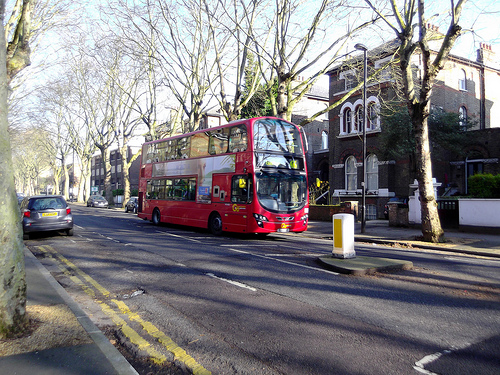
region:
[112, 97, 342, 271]
this is a bus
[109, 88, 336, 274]
the bus is a double decker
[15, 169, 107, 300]
car on side of the street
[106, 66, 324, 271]
the bus is red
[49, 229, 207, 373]
yellow lines on the street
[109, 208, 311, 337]
white lines on the street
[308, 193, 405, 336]
median in the street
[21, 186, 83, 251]
this is a car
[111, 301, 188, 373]
these are yellow lines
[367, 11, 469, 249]
this is a tree without leaves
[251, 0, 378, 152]
this is a tree without leaves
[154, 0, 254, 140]
this is a tree without leaves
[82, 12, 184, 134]
this is a tree without leaves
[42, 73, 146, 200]
this is a tree without leaves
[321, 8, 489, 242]
this is a building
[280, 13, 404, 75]
this is a branch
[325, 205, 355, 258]
white trash container on side of road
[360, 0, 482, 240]
large bare tree in the sunlight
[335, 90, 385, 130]
white framed windows on building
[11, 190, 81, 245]
dark gray compact car parked on road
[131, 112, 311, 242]
double stacked red travel bus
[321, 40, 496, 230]
large dark building next to buss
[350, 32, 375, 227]
tall light post in front of buiding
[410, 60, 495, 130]
shadow of building on the building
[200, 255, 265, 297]
white traffic line on asphalt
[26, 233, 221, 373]
double yellow line painted on asphalt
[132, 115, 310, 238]
Red double decker bus on the street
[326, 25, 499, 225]
Building with white trim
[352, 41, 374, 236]
Street lamp on the curb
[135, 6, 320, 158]
Trees behind a bus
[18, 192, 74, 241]
Grey car parked on the side of the road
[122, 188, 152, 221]
Car behind the bus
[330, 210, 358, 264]
White and yellow street marker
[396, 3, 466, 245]
Tree in front of a building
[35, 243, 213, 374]
Yellow lines on the street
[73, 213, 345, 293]
White lines on the street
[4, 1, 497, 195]
light in daytime sky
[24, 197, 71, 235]
back of parked car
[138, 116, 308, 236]
red double decker bus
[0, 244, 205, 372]
yellow lines on side of road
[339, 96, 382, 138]
three arched windows in a row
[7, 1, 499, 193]
trees with no leaves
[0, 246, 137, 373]
curb on edge of sidewalk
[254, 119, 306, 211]
windows on front of bus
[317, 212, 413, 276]
white post on cement platform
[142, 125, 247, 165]
row of bus windows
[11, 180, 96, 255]
This is a car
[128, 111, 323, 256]
This is a bus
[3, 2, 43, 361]
This is a tree